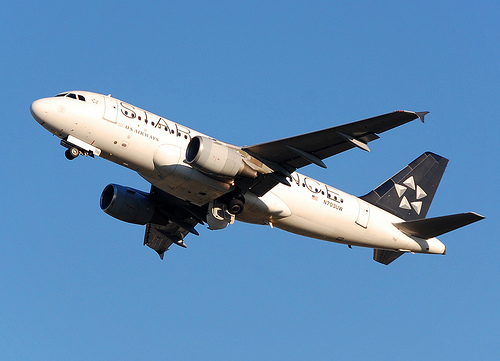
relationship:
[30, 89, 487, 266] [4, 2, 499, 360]
plane in sky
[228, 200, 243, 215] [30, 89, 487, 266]
wheel on plane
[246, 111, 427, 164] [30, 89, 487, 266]
wing on plane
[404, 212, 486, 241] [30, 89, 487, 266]
back wing on plane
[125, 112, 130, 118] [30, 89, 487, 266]
window on plane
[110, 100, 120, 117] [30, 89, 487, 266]
door on plane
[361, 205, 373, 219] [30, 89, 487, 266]
backdoor on plane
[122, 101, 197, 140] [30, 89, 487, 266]
logo on plane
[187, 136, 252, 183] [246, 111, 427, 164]
engine below wing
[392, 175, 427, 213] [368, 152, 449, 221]
logo on tail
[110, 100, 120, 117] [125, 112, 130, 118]
door next to window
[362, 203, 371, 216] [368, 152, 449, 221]
door near tail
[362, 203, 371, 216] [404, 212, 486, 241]
door near back wing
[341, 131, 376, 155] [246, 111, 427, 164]
slat under wing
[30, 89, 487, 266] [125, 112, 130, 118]
plane has window